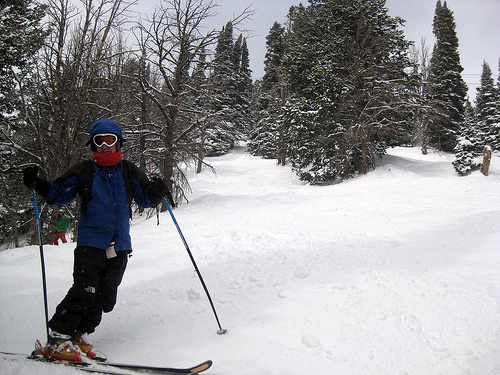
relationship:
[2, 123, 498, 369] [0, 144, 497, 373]
snow on ground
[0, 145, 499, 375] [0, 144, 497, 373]
snow on ground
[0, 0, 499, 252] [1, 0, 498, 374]
trees have snow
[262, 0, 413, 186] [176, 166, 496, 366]
tree have snow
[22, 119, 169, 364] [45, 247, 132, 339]
he wearing black pants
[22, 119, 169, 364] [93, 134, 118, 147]
he wearing goggles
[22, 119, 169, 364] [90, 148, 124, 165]
he has scarf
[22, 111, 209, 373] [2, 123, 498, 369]
woman on snow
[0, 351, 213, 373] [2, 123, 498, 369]
skiis on snow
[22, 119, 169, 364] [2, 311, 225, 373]
he on skis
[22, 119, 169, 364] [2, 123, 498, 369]
he on snow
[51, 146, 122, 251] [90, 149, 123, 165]
scarf on neck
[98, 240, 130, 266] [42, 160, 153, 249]
tag hanging from jacket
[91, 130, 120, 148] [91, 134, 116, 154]
goggles on face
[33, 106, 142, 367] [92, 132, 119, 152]
he wears goggles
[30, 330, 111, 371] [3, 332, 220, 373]
feet on skiis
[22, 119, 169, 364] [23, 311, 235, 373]
he wears skis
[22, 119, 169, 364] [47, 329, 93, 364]
he wears boots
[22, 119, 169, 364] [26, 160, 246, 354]
he on skiis